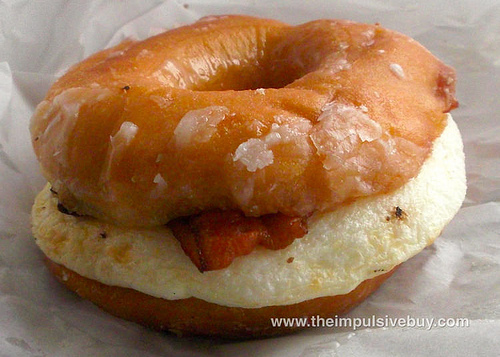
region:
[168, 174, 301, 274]
The bacon on the sandwich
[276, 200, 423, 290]
The egg is on the sandwich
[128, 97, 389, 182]
The doughnut on top of the sandwich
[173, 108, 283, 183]
The sugar on the doughnut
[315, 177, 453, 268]
The egg is the color white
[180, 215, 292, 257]
The bacon is the color brown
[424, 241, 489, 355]
The color of the paper is white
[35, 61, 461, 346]
The shape of the sandwich is round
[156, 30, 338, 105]
The hole in the doughnut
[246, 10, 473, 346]
Half of the breakfast sandwich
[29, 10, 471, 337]
An egg breakfast sandwich.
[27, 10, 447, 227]
Half of a bun.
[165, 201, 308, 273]
A piece of bacon.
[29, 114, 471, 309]
A cooked egg white.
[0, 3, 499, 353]
A white food wrapper.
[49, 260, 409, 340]
Half of a sandwhich roll.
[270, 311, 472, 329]
A website address.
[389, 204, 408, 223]
A small burnt area.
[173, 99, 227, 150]
An area of white.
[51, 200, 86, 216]
A piece of meat.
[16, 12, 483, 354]
Glazed donut breakfast sandwich.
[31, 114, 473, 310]
Egg on breakfast sandwich.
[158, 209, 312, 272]
Bacon on top of egg.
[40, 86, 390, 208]
Sugar glaze on donut.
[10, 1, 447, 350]
Breakfast sandwich on white wax paper.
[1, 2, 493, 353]
White wax paper with a sandwich on it.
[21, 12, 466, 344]
Sandwich made from a donut.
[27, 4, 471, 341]
Egg and bacon between donut halves.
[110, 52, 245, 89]
Light shining on donut glaze.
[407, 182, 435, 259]
This is a piece of very cooked egg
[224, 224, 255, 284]
This is a piece of very hot bacon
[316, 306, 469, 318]
The words on the bottom of the photo are www.theimpulsivebuy.com.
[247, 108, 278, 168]
There is a glazed donut that is here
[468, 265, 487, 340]
There is some wrapping here to keep the sandwich fresh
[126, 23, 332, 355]
This photo is of a very precise quality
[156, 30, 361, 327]
This photo was taken with a telephoto lens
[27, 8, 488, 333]
bacon and egg sandwich on a donut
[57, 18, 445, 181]
glazed donut with white glaze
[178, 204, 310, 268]
folded piece of bacon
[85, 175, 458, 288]
bacon and egg in between a donut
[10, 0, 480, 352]
white wax paper under sandwich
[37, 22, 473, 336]
breakfast sandwich on a donut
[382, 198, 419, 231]
black piece of pepper on egg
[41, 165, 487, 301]
fried egg with bacon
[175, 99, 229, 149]
white glazed on donut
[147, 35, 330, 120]
hole in the center of the donut